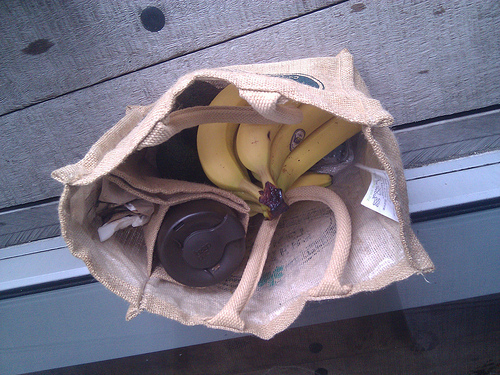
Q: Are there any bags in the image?
A: Yes, there is a bag.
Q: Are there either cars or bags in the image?
A: Yes, there is a bag.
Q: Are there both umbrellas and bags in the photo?
A: No, there is a bag but no umbrellas.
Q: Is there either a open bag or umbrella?
A: Yes, there is an open bag.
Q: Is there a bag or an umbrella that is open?
A: Yes, the bag is open.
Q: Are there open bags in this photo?
A: Yes, there is an open bag.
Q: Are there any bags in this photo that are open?
A: Yes, there is a bag that is open.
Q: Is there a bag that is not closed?
A: Yes, there is a open bag.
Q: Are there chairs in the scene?
A: No, there are no chairs.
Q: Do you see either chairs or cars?
A: No, there are no chairs or cars.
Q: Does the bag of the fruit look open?
A: Yes, the bag is open.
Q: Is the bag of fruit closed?
A: No, the bag is open.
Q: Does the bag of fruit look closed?
A: No, the bag is open.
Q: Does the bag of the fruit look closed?
A: No, the bag is open.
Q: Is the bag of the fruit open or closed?
A: The bag is open.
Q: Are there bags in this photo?
A: Yes, there is a bag.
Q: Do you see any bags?
A: Yes, there is a bag.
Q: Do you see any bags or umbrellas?
A: Yes, there is a bag.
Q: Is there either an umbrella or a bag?
A: Yes, there is a bag.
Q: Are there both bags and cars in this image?
A: No, there is a bag but no cars.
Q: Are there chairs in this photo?
A: No, there are no chairs.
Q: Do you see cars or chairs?
A: No, there are no chairs or cars.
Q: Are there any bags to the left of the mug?
A: Yes, there is a bag to the left of the mug.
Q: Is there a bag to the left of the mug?
A: Yes, there is a bag to the left of the mug.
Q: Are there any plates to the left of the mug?
A: No, there is a bag to the left of the mug.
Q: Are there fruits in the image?
A: Yes, there is a fruit.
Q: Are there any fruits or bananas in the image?
A: Yes, there is a fruit.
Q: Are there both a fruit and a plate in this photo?
A: No, there is a fruit but no plates.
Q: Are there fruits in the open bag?
A: Yes, there is a fruit in the bag.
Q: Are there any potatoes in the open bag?
A: No, there is a fruit in the bag.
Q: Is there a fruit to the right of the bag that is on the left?
A: Yes, there is a fruit to the right of the bag.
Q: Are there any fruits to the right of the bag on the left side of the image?
A: Yes, there is a fruit to the right of the bag.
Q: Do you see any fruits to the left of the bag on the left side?
A: No, the fruit is to the right of the bag.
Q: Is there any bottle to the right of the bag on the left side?
A: No, there is a fruit to the right of the bag.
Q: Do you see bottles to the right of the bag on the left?
A: No, there is a fruit to the right of the bag.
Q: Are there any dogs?
A: No, there are no dogs.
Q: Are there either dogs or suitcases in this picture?
A: No, there are no dogs or suitcases.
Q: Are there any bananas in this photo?
A: Yes, there is a banana.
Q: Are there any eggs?
A: No, there are no eggs.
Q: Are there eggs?
A: No, there are no eggs.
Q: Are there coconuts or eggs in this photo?
A: No, there are no eggs or coconuts.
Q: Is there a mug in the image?
A: Yes, there is a mug.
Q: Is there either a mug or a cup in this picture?
A: Yes, there is a mug.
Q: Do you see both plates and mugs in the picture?
A: No, there is a mug but no plates.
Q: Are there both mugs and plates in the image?
A: No, there is a mug but no plates.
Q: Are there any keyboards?
A: No, there are no keyboards.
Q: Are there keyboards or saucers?
A: No, there are no keyboards or saucers.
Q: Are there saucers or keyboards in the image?
A: No, there are no keyboards or saucers.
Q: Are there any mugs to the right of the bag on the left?
A: Yes, there is a mug to the right of the bag.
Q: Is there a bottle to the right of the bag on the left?
A: No, there is a mug to the right of the bag.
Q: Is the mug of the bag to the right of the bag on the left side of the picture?
A: Yes, the mug is to the right of the bag.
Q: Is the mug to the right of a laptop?
A: No, the mug is to the right of the bag.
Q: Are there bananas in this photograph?
A: Yes, there is a banana.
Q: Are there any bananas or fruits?
A: Yes, there is a banana.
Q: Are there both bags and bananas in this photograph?
A: Yes, there are both a banana and a bag.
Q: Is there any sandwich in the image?
A: No, there are no sandwiches.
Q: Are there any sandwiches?
A: No, there are no sandwiches.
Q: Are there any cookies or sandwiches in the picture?
A: No, there are no sandwiches or cookies.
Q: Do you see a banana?
A: Yes, there is a banana.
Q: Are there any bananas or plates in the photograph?
A: Yes, there is a banana.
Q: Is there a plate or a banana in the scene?
A: Yes, there is a banana.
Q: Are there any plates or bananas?
A: Yes, there is a banana.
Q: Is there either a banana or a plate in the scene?
A: Yes, there is a banana.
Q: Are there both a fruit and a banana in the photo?
A: Yes, there are both a banana and a fruit.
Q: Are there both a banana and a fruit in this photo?
A: Yes, there are both a banana and a fruit.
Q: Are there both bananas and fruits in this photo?
A: Yes, there are both a banana and a fruit.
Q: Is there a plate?
A: No, there are no plates.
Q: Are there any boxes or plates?
A: No, there are no plates or boxes.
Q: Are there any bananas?
A: Yes, there is a banana.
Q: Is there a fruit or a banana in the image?
A: Yes, there is a banana.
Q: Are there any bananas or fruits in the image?
A: Yes, there is a banana.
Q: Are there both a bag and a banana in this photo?
A: Yes, there are both a banana and a bag.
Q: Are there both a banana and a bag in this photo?
A: Yes, there are both a banana and a bag.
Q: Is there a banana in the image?
A: Yes, there is a banana.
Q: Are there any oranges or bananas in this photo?
A: Yes, there is a banana.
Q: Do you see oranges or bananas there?
A: Yes, there is a banana.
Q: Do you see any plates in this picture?
A: No, there are no plates.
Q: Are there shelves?
A: No, there are no shelves.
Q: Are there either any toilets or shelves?
A: No, there are no shelves or toilets.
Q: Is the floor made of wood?
A: Yes, the floor is made of wood.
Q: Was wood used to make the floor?
A: Yes, the floor is made of wood.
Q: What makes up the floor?
A: The floor is made of wood.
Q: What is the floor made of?
A: The floor is made of wood.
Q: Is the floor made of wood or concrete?
A: The floor is made of wood.